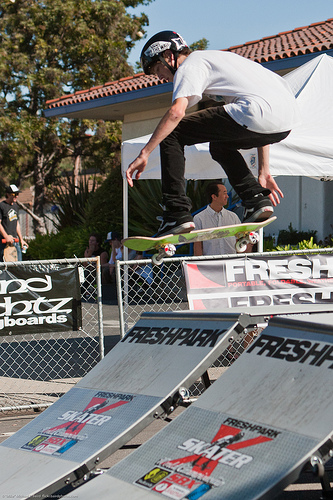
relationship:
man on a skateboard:
[125, 32, 296, 237] [115, 215, 279, 264]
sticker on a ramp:
[5, 385, 161, 464] [3, 311, 245, 499]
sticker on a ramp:
[105, 404, 321, 497] [55, 311, 332, 499]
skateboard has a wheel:
[115, 215, 279, 264] [153, 252, 164, 266]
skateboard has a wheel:
[115, 215, 279, 264] [162, 242, 177, 256]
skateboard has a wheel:
[115, 215, 279, 264] [236, 240, 248, 252]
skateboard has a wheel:
[115, 215, 279, 264] [249, 232, 260, 243]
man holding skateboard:
[1, 183, 30, 262] [1, 237, 22, 264]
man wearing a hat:
[1, 183, 30, 262] [5, 183, 21, 195]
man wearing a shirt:
[1, 183, 30, 262] [0, 200, 20, 240]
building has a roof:
[41, 15, 331, 242] [41, 18, 331, 119]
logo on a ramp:
[121, 326, 226, 351] [3, 311, 245, 499]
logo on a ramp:
[247, 335, 332, 371] [55, 311, 332, 499]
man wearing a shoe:
[125, 32, 296, 237] [155, 213, 195, 239]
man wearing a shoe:
[125, 32, 296, 237] [240, 195, 275, 224]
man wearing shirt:
[1, 183, 30, 262] [0, 200, 20, 240]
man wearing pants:
[125, 32, 296, 237] [161, 108, 292, 216]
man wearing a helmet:
[125, 32, 296, 237] [142, 31, 187, 76]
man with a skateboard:
[125, 32, 296, 237] [115, 215, 279, 264]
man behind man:
[125, 32, 296, 237] [192, 182, 246, 257]